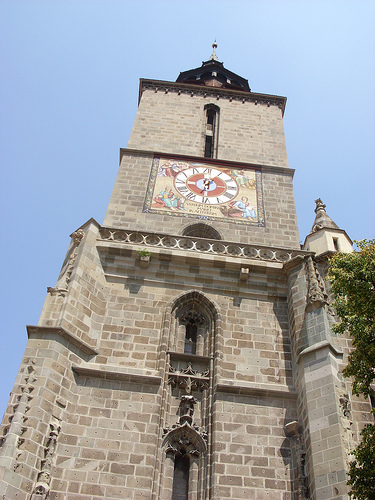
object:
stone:
[247, 355, 269, 367]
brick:
[124, 326, 141, 335]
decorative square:
[142, 151, 267, 228]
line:
[188, 181, 196, 186]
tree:
[323, 237, 375, 500]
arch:
[158, 420, 207, 499]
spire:
[207, 36, 218, 62]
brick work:
[0, 327, 70, 500]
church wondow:
[203, 102, 221, 158]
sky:
[0, 0, 375, 425]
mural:
[142, 154, 266, 230]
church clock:
[173, 164, 240, 206]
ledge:
[88, 225, 315, 297]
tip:
[207, 36, 223, 62]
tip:
[314, 197, 327, 213]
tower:
[298, 198, 353, 255]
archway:
[149, 290, 221, 497]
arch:
[177, 220, 226, 241]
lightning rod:
[201, 36, 224, 65]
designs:
[143, 288, 221, 500]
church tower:
[0, 37, 375, 500]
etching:
[0, 362, 67, 500]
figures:
[141, 156, 266, 229]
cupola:
[302, 197, 354, 254]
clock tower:
[0, 36, 375, 500]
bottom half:
[0, 215, 375, 500]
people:
[156, 158, 192, 179]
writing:
[185, 201, 220, 216]